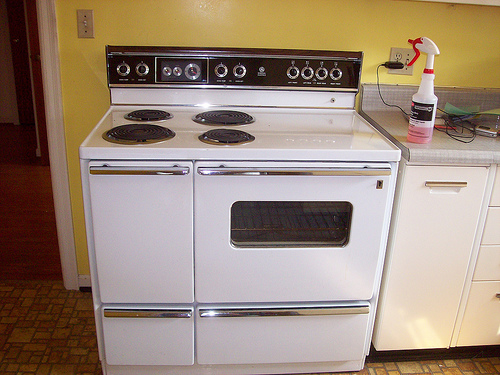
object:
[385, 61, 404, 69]
black plug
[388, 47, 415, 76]
outlet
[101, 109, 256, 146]
burners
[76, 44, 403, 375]
stove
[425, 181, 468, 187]
handle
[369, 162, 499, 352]
cabinet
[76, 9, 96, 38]
switch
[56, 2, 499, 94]
wall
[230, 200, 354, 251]
window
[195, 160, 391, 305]
oven door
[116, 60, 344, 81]
knobs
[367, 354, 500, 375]
tiles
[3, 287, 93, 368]
tiles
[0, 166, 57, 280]
floor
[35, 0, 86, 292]
doorway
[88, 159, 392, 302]
oven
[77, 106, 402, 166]
stove top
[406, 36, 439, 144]
bottle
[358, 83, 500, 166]
counter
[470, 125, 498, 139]
cell phone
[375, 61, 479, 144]
phone charger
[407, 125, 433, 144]
cleaning agent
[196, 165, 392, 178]
handle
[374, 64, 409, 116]
cord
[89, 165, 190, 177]
handle